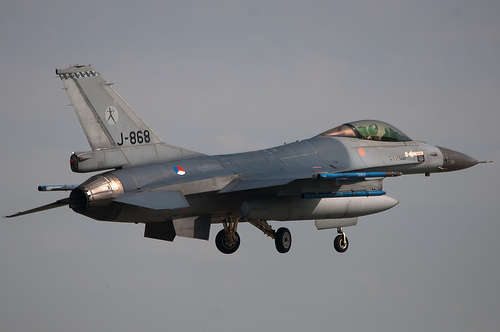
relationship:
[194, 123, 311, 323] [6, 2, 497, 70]
jet in sky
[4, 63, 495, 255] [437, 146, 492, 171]
jet has nose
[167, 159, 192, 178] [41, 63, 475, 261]
logo of plane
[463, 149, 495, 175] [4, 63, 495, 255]
nose point of jet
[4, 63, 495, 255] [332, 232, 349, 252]
jet has wheel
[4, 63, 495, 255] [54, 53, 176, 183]
jet has vertical stabilizer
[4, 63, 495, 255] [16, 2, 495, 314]
jet in sky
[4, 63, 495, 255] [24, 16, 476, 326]
jet in sky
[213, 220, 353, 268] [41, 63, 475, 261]
wheels under plane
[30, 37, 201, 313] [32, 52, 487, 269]
tail of plane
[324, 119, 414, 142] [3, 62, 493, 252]
cockpit of plane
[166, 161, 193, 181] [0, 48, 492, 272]
circle on plane